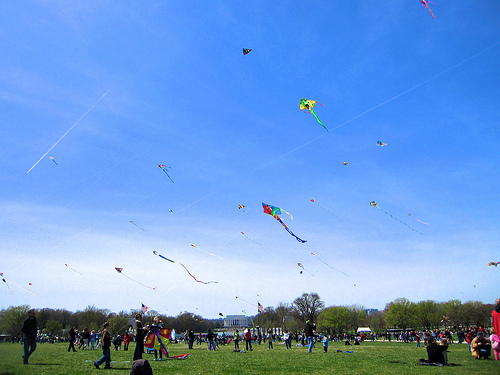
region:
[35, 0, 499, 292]
the lites flying in the air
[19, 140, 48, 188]
a trail in the sky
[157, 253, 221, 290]
the waving sting of the kite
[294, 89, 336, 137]
a yellow and green kite in the air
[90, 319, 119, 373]
the boy holds onto the kite string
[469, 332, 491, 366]
a person in a brown jacket croutching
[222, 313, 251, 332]
washington monument in the background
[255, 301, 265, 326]
the american flag waving in the wind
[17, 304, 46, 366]
a man with his hands in his pockets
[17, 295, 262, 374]
people gather to fly kites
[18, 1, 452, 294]
kites flying in the sky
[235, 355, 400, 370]
green grass at a park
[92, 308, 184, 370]
people flying kites in sky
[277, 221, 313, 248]
tail of a kite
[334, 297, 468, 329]
trees in the back of park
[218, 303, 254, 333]
building in the distance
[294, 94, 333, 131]
yellow and green kite in sky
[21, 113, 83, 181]
streak in the air from plane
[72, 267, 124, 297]
white clouds in the sky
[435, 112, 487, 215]
blue sky in the distance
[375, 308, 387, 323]
part of a bush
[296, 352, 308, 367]
part of a lawn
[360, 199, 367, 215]
part of the sky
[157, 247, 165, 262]
part of a kite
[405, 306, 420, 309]
part of a forest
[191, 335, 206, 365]
part of a lawn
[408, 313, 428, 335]
part of a crowd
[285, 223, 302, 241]
part of a kite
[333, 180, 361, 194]
part of the cloud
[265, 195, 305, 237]
green and red kite in air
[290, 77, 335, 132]
yellow and green kite in air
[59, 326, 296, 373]
short green grass below people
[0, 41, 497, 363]
people flying kites in park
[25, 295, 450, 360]
trees around perimeter of park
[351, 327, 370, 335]
white tent in distance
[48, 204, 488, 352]
thin clouds in background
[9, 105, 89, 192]
jet passing overhead of park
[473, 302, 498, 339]
person in red shirt on right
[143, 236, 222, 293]
kite flying with long tail